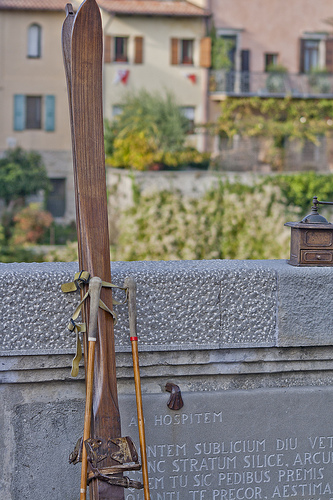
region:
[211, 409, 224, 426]
letter on the marble slab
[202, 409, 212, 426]
letter on the marble slab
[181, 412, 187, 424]
letter on the marble slab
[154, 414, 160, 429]
letter on the marble slab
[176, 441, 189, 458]
letter on the marble slab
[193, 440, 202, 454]
letter on the marble slab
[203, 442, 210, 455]
letter on the marble slab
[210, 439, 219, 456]
letter on the marble slab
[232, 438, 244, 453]
letter on the marble slab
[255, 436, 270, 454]
letter on the marble slab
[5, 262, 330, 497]
gray block with inscription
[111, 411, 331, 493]
inscription on the side of gray stone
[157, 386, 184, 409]
bracket holding gray plaque to stone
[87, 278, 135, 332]
grand handles of ski poles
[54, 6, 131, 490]
brown skis tied together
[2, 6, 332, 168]
two buildings in the background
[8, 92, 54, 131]
green shutters on left side building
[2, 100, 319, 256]
shrubbery and plants around buildings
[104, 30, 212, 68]
brown shutters on left side building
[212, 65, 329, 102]
black balcony of building on the right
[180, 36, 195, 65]
blurry window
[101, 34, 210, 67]
two windows with brown shutters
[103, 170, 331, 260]
vines growing on a wall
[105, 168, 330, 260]
a gray colored concrete wall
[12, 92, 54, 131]
window with green shutters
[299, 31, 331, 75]
window with dark brown shutter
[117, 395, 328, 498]
plaque on a monument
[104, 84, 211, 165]
bush with green and yellow leaves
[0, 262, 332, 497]
gray colored concrete monument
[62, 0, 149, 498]
two old skis and ski poles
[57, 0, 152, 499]
A pair of skis and ski poles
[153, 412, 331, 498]
Inscription on a wall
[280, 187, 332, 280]
A coffee grinder on a wall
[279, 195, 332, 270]
An antique coffee grinder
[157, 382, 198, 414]
A wrought iron clasp holding a placard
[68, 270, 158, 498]
A pair of ski sticks leaning on a wall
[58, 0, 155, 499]
A set of skis leaning against a concrete wall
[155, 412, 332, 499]
Roman inscription on a wall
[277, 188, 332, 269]
An antique bean grinder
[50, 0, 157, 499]
An antique set of skis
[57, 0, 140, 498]
very old pair of skis standing up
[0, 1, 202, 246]
old building behind the wall where the skis are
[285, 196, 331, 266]
a wooden grinder on top of wall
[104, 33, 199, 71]
windows on old building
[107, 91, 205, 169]
trees in the background behind wall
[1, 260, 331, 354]
top part of wall where old skis lay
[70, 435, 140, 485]
straps where you put your foot in ski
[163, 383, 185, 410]
iron tab holding plack on wall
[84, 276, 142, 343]
top of both ski poles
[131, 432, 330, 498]
ingrave words on wall where skis are